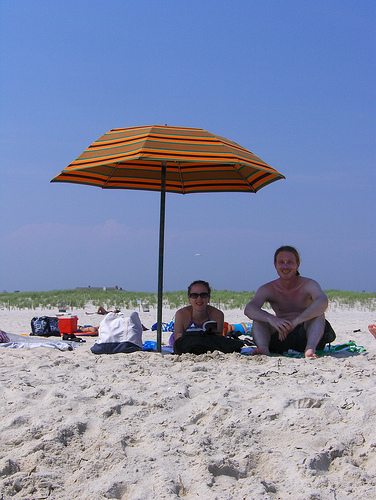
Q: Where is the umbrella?
A: Next to the people.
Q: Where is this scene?
A: Beach.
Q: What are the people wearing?
A: Swimsuits.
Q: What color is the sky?
A: Blue.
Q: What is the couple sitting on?
A: Sand.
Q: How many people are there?
A: Two.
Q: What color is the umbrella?
A: Orange.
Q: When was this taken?
A: During the day.